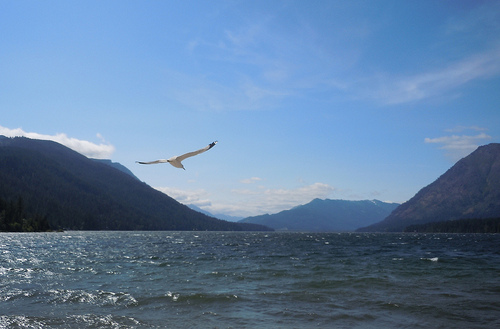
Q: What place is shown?
A: It is an ocean.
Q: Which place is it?
A: It is an ocean.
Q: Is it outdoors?
A: Yes, it is outdoors.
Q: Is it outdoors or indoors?
A: It is outdoors.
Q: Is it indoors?
A: No, it is outdoors.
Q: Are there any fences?
A: No, there are no fences.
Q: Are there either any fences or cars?
A: No, there are no fences or cars.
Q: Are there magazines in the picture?
A: No, there are no magazines.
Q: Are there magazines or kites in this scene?
A: No, there are no magazines or kites.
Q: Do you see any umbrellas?
A: No, there are no umbrellas.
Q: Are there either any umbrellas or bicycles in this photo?
A: No, there are no umbrellas or bicycles.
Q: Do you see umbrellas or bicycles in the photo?
A: No, there are no umbrellas or bicycles.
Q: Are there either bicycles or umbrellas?
A: No, there are no umbrellas or bicycles.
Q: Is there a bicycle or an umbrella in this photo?
A: No, there are no umbrellas or bicycles.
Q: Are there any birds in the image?
A: Yes, there is a bird.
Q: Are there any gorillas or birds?
A: Yes, there is a bird.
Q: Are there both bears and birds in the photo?
A: No, there is a bird but no bears.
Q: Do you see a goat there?
A: No, there are no goats.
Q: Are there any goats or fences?
A: No, there are no goats or fences.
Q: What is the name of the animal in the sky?
A: The animal is a bird.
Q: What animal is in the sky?
A: The animal is a bird.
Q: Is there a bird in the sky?
A: Yes, there is a bird in the sky.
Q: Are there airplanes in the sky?
A: No, there is a bird in the sky.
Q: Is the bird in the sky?
A: Yes, the bird is in the sky.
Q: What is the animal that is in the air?
A: The animal is a bird.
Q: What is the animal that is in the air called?
A: The animal is a bird.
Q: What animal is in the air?
A: The animal is a bird.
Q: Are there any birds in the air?
A: Yes, there is a bird in the air.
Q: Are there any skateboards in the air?
A: No, there is a bird in the air.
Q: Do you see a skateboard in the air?
A: No, there is a bird in the air.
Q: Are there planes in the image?
A: No, there are no planes.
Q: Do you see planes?
A: No, there are no planes.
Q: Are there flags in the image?
A: No, there are no flags.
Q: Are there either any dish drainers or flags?
A: No, there are no flags or dish drainers.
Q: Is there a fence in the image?
A: No, there are no fences.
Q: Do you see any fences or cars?
A: No, there are no fences or cars.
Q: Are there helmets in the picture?
A: No, there are no helmets.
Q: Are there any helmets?
A: No, there are no helmets.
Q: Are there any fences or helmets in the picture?
A: No, there are no helmets or fences.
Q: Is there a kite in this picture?
A: No, there are no kites.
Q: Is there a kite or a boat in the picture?
A: No, there are no kites or boats.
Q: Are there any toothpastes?
A: No, there are no toothpastes.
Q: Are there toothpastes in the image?
A: No, there are no toothpastes.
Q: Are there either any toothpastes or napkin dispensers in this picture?
A: No, there are no toothpastes or napkin dispensers.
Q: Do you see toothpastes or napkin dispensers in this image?
A: No, there are no toothpastes or napkin dispensers.